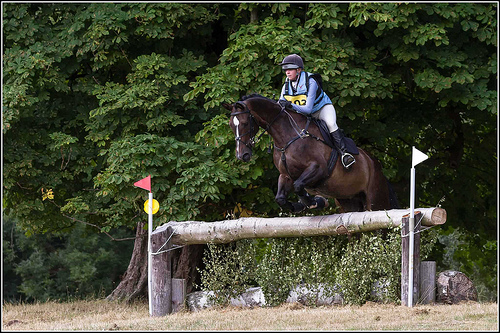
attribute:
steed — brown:
[227, 93, 381, 220]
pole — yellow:
[130, 194, 187, 232]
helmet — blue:
[274, 51, 303, 68]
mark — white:
[231, 113, 242, 134]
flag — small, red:
[126, 174, 187, 206]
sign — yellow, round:
[136, 184, 176, 227]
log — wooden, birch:
[151, 218, 445, 260]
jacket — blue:
[289, 80, 339, 116]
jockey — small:
[270, 34, 331, 144]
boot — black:
[318, 120, 354, 166]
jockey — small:
[259, 49, 377, 174]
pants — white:
[311, 103, 339, 133]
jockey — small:
[254, 42, 354, 154]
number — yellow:
[276, 89, 312, 107]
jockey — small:
[272, 34, 350, 154]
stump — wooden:
[141, 217, 191, 303]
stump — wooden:
[167, 243, 205, 312]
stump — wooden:
[420, 251, 444, 321]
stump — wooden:
[139, 207, 453, 250]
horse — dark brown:
[214, 76, 383, 237]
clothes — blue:
[278, 79, 341, 122]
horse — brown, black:
[225, 91, 390, 220]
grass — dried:
[4, 298, 499, 331]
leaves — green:
[4, 0, 499, 292]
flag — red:
[130, 170, 153, 192]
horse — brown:
[225, 86, 394, 212]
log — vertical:
[154, 202, 448, 252]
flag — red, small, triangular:
[130, 168, 152, 193]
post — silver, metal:
[147, 189, 152, 317]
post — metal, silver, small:
[409, 162, 417, 309]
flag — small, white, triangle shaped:
[407, 145, 433, 172]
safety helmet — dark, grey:
[280, 49, 306, 74]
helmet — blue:
[281, 49, 311, 71]